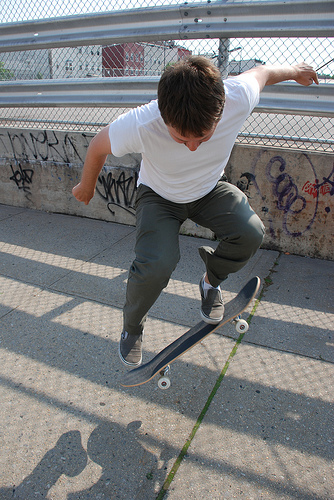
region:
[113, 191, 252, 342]
the pants are gray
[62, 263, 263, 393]
the skateboard is black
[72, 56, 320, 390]
a boy on skate board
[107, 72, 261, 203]
boy wearing white t-shirt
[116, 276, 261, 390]
a blue skate board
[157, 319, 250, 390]
a skate board with white wheels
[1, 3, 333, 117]
metal rails on concrete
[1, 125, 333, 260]
a large slab of concrete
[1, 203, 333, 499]
a large concrete platform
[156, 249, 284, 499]
line of grass between concrete blocks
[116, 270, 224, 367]
pair of gray and white tennis shoes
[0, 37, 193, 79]
red and white building in back ground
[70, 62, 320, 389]
a skateboarder performing trick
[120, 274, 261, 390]
a brown and black skateboard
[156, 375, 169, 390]
a white skateboard wheel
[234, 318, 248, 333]
a white skateboard wheel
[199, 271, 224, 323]
a man's grey shoe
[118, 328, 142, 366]
a man's grey shoe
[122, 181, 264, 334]
a pair of grey pants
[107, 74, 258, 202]
a man's white t-shirt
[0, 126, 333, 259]
a short concrete wall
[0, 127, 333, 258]
a graffiti covered wall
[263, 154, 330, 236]
tagging on the wall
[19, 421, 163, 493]
a shadow on the ground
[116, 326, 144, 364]
grey and white shoes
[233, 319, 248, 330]
a white wheel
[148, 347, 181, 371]
a skateboard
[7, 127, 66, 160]
black tagging on the wall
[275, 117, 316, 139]
a fence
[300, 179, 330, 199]
red taggin on the wall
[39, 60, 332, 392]
a man jumping a skateboard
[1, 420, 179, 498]
the shadow of a man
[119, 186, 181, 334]
the leg of a man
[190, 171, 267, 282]
the leg of a man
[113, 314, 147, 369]
the foot of a man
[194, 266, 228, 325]
the foot of a man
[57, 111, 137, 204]
the arm of a man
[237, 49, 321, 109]
the arm of a man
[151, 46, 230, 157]
the head of a man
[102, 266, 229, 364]
the feet of a man